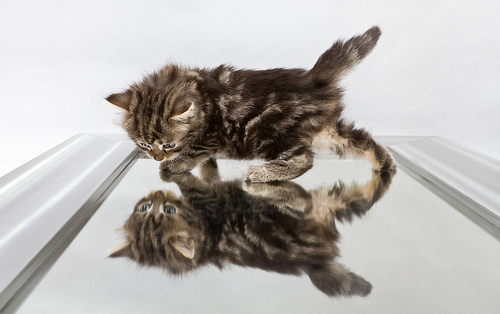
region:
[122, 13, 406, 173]
A cat standing in the mirror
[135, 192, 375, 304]
Shadow of the cat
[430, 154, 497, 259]
A mirror with wood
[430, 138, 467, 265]
White color wood with glass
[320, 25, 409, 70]
Tail of the cat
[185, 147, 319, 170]
Legs of the cat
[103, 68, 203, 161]
Head of the cat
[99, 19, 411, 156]
Brown, black and white color of the dog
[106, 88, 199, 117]
Ears of the cat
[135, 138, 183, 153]
Eyes of the cat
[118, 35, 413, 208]
a cat walking on a glass surface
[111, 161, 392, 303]
reflection of the cat on the glass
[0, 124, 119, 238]
white wood edge of the table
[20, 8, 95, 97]
white wall of the room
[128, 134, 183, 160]
blue eyes of the kitten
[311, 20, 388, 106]
standing furry tail of the cat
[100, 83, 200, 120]
pointed ears of the cat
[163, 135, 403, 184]
the legs of the kitten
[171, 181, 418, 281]
smooth glass surface of the table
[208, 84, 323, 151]
black and white stripes in the cat's fur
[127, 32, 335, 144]
this is a cat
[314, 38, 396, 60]
this is the tail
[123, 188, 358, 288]
this is the image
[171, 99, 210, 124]
this is the ear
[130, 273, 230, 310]
this is a glass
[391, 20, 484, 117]
this is a wall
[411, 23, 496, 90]
the wall is white in color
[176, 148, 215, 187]
this is the leg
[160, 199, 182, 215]
this is the eye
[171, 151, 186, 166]
these are the fur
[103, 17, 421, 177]
a small grey cat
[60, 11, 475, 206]
a very cute kitten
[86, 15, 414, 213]
a grey kitten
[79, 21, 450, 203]
the kitten has stripes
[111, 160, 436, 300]
the reflection of the kitten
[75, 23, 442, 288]
the kitten is looking in a mirror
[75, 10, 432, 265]
the kitten sees its reflection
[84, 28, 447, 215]
the kitten has black stripes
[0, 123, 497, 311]
the mirror has a white frame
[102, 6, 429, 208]
a very small grey and black kitten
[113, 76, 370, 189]
a stripes, cute kitten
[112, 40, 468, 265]
a stripes, cute kitten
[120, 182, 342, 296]
a reflection of a kitten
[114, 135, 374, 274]
a reflection of a kitten